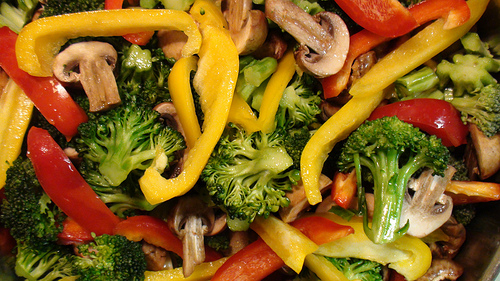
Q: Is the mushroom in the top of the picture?
A: Yes, the mushroom is in the top of the image.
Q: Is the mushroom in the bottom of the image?
A: No, the mushroom is in the top of the image.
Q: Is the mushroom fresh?
A: Yes, the mushroom is fresh.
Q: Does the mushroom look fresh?
A: Yes, the mushroom is fresh.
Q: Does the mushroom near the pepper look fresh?
A: Yes, the mushroom is fresh.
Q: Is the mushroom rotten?
A: No, the mushroom is fresh.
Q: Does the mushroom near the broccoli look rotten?
A: No, the mushroom is fresh.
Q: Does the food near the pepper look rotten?
A: No, the mushroom is fresh.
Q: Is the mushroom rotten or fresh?
A: The mushroom is fresh.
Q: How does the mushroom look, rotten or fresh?
A: The mushroom is fresh.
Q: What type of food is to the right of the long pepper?
A: The food is a mushroom.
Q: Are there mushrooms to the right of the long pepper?
A: Yes, there is a mushroom to the right of the pepper.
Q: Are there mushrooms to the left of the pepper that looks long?
A: No, the mushroom is to the right of the pepper.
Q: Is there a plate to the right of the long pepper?
A: No, there is a mushroom to the right of the pepper.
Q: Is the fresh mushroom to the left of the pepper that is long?
A: No, the mushroom is to the right of the pepper.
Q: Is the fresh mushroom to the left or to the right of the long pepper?
A: The mushroom is to the right of the pepper.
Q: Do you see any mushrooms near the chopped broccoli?
A: Yes, there is a mushroom near the broccoli.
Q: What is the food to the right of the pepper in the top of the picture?
A: The food is a mushroom.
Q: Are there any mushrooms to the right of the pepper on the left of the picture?
A: Yes, there is a mushroom to the right of the pepper.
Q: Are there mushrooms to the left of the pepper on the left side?
A: No, the mushroom is to the right of the pepper.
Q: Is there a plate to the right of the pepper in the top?
A: No, there is a mushroom to the right of the pepper.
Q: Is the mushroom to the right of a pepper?
A: Yes, the mushroom is to the right of a pepper.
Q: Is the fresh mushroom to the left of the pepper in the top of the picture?
A: No, the mushroom is to the right of the pepper.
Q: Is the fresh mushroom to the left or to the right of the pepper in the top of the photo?
A: The mushroom is to the right of the pepper.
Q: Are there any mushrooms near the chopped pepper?
A: Yes, there is a mushroom near the pepper.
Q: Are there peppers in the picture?
A: Yes, there is a pepper.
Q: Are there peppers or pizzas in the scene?
A: Yes, there is a pepper.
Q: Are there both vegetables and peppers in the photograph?
A: Yes, there are both a pepper and vegetables.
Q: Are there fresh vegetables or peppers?
A: Yes, there is a fresh pepper.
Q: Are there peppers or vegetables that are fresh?
A: Yes, the pepper is fresh.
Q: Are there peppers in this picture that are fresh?
A: Yes, there is a fresh pepper.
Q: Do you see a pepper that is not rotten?
A: Yes, there is a fresh pepper.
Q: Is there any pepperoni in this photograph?
A: No, there is no pepperoni.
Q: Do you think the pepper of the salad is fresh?
A: Yes, the pepper is fresh.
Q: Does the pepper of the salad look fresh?
A: Yes, the pepper is fresh.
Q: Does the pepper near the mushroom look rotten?
A: No, the pepper is fresh.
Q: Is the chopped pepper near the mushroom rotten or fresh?
A: The pepper is fresh.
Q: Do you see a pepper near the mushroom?
A: Yes, there is a pepper near the mushroom.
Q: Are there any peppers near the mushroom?
A: Yes, there is a pepper near the mushroom.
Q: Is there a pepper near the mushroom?
A: Yes, there is a pepper near the mushroom.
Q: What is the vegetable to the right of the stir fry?
A: The vegetable is a pepper.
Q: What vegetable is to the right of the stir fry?
A: The vegetable is a pepper.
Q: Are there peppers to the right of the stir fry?
A: Yes, there is a pepper to the right of the stir fry.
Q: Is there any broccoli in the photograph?
A: Yes, there is broccoli.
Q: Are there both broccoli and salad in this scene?
A: Yes, there are both broccoli and salad.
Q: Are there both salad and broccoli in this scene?
A: Yes, there are both broccoli and salad.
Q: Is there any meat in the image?
A: No, there is no meat.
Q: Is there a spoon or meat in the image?
A: No, there are no meat or spoons.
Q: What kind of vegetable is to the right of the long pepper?
A: The vegetable is broccoli.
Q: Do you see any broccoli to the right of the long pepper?
A: Yes, there is broccoli to the right of the pepper.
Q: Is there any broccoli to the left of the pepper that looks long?
A: No, the broccoli is to the right of the pepper.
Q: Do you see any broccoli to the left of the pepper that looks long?
A: No, the broccoli is to the right of the pepper.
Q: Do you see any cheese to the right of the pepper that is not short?
A: No, there is broccoli to the right of the pepper.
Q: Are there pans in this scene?
A: Yes, there is a pan.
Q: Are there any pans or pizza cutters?
A: Yes, there is a pan.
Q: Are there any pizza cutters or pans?
A: Yes, there is a pan.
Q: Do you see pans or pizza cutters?
A: Yes, there is a pan.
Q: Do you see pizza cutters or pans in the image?
A: Yes, there is a pan.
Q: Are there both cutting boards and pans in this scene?
A: No, there is a pan but no cutting boards.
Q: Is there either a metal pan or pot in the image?
A: Yes, there is a metal pan.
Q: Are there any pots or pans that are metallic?
A: Yes, the pan is metallic.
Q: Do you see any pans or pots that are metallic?
A: Yes, the pan is metallic.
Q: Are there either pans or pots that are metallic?
A: Yes, the pan is metallic.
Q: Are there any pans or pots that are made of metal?
A: Yes, the pan is made of metal.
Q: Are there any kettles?
A: No, there are no kettles.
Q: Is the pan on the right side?
A: Yes, the pan is on the right of the image.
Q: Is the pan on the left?
A: No, the pan is on the right of the image.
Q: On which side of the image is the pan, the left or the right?
A: The pan is on the right of the image.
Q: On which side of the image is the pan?
A: The pan is on the right of the image.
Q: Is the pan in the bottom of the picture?
A: Yes, the pan is in the bottom of the image.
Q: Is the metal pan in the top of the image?
A: No, the pan is in the bottom of the image.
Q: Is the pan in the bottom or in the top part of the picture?
A: The pan is in the bottom of the image.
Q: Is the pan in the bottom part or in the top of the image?
A: The pan is in the bottom of the image.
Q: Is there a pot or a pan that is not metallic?
A: No, there is a pan but it is metallic.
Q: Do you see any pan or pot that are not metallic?
A: No, there is a pan but it is metallic.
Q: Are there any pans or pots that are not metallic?
A: No, there is a pan but it is metallic.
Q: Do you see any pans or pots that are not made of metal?
A: No, there is a pan but it is made of metal.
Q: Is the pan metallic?
A: Yes, the pan is metallic.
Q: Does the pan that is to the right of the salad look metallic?
A: Yes, the pan is metallic.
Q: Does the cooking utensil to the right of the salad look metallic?
A: Yes, the pan is metallic.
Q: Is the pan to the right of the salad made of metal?
A: Yes, the pan is made of metal.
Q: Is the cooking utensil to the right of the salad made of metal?
A: Yes, the pan is made of metal.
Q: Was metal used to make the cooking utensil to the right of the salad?
A: Yes, the pan is made of metal.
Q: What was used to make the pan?
A: The pan is made of metal.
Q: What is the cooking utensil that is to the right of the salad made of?
A: The pan is made of metal.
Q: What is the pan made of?
A: The pan is made of metal.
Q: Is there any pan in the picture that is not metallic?
A: No, there is a pan but it is metallic.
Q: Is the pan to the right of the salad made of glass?
A: No, the pan is made of metal.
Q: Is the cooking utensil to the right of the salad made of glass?
A: No, the pan is made of metal.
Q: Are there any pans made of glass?
A: No, there is a pan but it is made of metal.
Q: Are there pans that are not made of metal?
A: No, there is a pan but it is made of metal.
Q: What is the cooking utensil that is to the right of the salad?
A: The cooking utensil is a pan.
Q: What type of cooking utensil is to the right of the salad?
A: The cooking utensil is a pan.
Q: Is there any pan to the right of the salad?
A: Yes, there is a pan to the right of the salad.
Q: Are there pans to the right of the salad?
A: Yes, there is a pan to the right of the salad.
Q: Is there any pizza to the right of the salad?
A: No, there is a pan to the right of the salad.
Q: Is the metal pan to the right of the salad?
A: Yes, the pan is to the right of the salad.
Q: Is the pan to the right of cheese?
A: No, the pan is to the right of the salad.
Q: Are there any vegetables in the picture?
A: Yes, there are vegetables.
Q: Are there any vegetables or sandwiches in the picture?
A: Yes, there are vegetables.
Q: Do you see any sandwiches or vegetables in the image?
A: Yes, there are vegetables.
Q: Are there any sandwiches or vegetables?
A: Yes, there are vegetables.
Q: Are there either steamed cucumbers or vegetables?
A: Yes, there are steamed vegetables.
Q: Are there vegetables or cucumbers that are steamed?
A: Yes, the vegetables are steamed.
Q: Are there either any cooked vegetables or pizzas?
A: Yes, there are cooked vegetables.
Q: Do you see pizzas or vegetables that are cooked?
A: Yes, the vegetables are cooked.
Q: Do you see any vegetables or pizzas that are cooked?
A: Yes, the vegetables are cooked.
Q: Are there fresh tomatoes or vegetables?
A: Yes, there are fresh vegetables.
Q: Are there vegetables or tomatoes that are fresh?
A: Yes, the vegetables are fresh.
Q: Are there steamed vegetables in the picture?
A: Yes, there are steamed vegetables.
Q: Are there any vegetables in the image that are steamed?
A: Yes, there are vegetables that are steamed.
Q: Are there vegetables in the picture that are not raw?
A: Yes, there are steamed vegetables.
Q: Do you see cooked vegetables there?
A: Yes, there are cooked vegetables.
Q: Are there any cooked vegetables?
A: Yes, there are cooked vegetables.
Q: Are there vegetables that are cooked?
A: Yes, there are vegetables that are cooked.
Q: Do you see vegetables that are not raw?
A: Yes, there are cooked vegetables.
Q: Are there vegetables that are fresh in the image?
A: Yes, there are fresh vegetables.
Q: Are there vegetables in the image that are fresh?
A: Yes, there are vegetables that are fresh.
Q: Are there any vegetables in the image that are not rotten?
A: Yes, there are fresh vegetables.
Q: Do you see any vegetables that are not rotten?
A: Yes, there are fresh vegetables.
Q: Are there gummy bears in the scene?
A: No, there are no gummy bears.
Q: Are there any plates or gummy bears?
A: No, there are no gummy bears or plates.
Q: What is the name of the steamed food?
A: The food is vegetables.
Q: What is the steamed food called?
A: The food is vegetables.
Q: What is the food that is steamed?
A: The food is vegetables.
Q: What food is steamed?
A: The food is vegetables.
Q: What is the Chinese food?
A: The food is vegetables.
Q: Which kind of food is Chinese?
A: The food is vegetables.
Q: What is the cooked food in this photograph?
A: The food is vegetables.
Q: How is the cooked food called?
A: The food is vegetables.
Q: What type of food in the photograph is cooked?
A: The food is vegetables.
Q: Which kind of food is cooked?
A: The food is vegetables.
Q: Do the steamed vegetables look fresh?
A: Yes, the veggies are fresh.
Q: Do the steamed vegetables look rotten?
A: No, the veggies are fresh.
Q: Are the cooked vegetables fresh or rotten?
A: The veggies are fresh.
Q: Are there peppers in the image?
A: Yes, there is a pepper.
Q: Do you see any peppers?
A: Yes, there is a pepper.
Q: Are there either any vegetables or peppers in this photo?
A: Yes, there is a pepper.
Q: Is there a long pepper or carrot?
A: Yes, there is a long pepper.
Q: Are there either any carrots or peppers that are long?
A: Yes, the pepper is long.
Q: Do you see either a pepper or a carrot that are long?
A: Yes, the pepper is long.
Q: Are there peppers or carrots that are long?
A: Yes, the pepper is long.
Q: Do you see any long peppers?
A: Yes, there is a long pepper.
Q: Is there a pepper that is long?
A: Yes, there is a pepper that is long.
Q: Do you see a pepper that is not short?
A: Yes, there is a long pepper.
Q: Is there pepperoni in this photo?
A: No, there is no pepperoni.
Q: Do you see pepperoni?
A: No, there is no pepperoni.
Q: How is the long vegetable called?
A: The vegetable is a pepper.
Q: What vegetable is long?
A: The vegetable is a pepper.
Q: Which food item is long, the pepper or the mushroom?
A: The pepper is long.